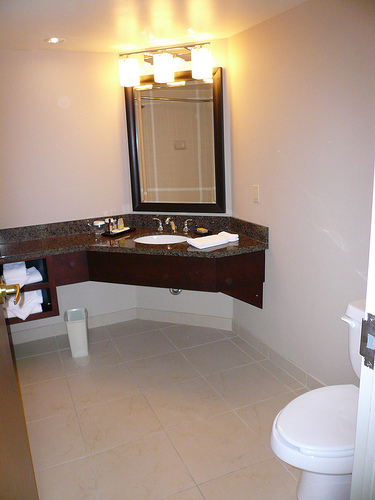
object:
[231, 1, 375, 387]
wall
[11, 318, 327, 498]
floor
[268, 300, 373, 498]
toilet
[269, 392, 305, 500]
edge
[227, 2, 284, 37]
edge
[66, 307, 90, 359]
trash bin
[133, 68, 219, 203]
mirror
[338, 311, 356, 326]
plastic handle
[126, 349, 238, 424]
tile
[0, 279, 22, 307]
door handle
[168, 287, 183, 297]
pipe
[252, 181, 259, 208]
outlet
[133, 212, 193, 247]
sink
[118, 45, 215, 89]
light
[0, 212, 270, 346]
counter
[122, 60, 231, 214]
frame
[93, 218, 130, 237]
toiletries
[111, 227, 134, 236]
tray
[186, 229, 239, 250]
towels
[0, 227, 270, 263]
counter top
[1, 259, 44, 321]
towels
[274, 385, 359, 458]
lid